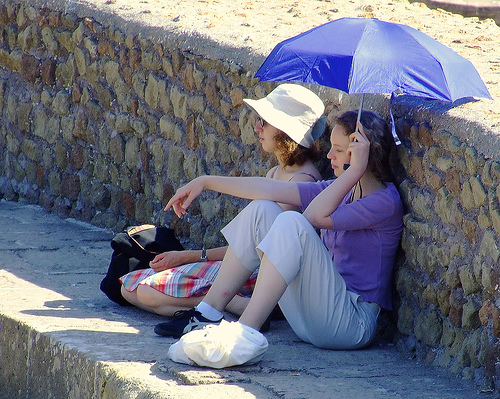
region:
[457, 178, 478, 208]
Small grey brick on a wall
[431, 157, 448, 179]
Small grey brick on a wall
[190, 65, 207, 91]
Small grey brick on a wall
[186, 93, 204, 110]
Small grey brick on a wall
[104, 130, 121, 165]
Small grey brick on a wall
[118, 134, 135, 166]
Small grey brick on a wall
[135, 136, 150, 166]
Small grey brick on a wall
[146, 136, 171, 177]
Small grey brick on a wall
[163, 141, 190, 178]
Small grey brick on a wall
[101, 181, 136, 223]
Small grey brick on a wall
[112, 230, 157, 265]
a black bag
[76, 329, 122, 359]
a shadow on the ground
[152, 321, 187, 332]
black shoe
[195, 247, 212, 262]
a watch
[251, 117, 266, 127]
the women is wearing eye glasses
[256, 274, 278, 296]
a leg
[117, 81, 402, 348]
the two girls sitting down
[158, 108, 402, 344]
the girl wearing a purple shirt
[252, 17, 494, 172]
the opened umbrella above the girl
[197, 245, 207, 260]
the watch on the girls arm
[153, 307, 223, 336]
the shoe on the girl's foot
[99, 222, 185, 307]
the bag next to the girl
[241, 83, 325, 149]
the hat on the girl's head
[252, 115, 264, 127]
the glasses on the girl's face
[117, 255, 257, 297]
the colorful skirt on the girl sitting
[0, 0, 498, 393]
the wall the girls are leaning on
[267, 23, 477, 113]
top of blue umbrella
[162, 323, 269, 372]
bag on the ground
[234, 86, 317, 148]
hat on the woman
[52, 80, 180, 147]
bricks on the wall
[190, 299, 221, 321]
sock on the woman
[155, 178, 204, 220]
hand of the woman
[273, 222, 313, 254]
knee of hte woman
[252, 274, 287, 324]
leg of the woman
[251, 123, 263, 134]
nose of the woman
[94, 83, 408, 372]
Two girls sitting by a stone wall.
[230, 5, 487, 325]
Girl holding an umbrella.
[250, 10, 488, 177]
A blue umbrella is being held for shade.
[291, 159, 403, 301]
A girl wearing a purple shirt.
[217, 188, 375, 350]
The girl is wearing tan pants.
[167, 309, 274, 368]
A package on the sidewalk.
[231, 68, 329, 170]
Girl wearing a white sun hat.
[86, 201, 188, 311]
Back pack on the sidewalk.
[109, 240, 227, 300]
Girl wearing a striped skirt.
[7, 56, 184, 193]
Wall made of many stones.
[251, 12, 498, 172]
blue umbrella in the woman's hand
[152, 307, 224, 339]
the girl's right shoe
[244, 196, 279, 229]
the girl's right knee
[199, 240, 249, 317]
the girl's right leg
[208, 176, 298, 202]
the girl's right arm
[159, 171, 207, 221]
the girl's right hand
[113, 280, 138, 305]
the girl's right knee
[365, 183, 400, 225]
the girl's left shoulder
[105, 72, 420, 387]
a pair of women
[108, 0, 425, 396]
the women are sitting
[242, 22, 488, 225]
woman holding an umbrella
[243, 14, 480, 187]
the umbrella is blue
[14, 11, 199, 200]
a stone rock wall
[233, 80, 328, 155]
woman wearing a white hat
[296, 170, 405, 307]
woman wearing a purple shirt